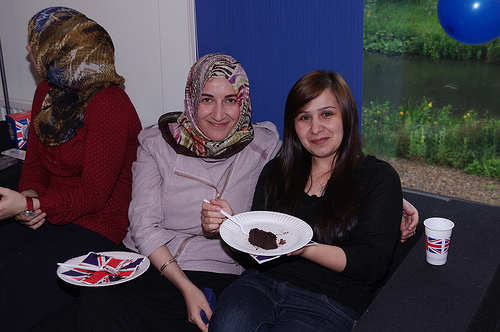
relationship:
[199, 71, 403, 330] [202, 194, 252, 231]
person using fork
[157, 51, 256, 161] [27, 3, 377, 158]
material have scarves on head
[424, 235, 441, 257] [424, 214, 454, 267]
british flag on cup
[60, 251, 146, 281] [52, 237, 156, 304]
flag on plate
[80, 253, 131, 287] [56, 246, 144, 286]
crumbs on napkin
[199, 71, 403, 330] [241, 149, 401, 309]
person wearing shirt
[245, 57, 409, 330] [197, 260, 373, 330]
person wearing jeans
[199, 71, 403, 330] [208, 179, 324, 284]
person holding plate.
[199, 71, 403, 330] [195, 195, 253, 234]
person holding fork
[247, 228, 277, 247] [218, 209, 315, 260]
cake on plate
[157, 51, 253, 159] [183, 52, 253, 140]
material wrapped around head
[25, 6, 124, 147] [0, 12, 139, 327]
material wrapped around person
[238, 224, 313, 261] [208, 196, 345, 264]
cake on plate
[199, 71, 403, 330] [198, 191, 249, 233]
person holding fork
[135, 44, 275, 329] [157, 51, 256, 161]
person wearing material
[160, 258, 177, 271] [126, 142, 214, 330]
band on arm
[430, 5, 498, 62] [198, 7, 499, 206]
balloon near window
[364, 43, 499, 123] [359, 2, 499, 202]
waterway outside window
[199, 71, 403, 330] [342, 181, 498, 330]
person sitting on sofa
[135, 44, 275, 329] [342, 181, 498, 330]
person sitting on sofa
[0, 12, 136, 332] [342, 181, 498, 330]
person sitting on sofa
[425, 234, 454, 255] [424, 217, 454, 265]
design on cup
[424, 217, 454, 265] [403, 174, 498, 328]
cup sitting on sofa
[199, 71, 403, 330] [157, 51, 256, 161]
person wearing material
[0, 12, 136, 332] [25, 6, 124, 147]
person wearing material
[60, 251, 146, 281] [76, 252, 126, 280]
flag laying on flag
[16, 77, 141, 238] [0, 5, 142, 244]
red blouse on woman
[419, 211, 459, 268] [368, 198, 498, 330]
cup sitting on ledge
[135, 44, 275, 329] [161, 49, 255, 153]
person wearing a wrap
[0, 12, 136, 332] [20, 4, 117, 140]
person wearing a wrap